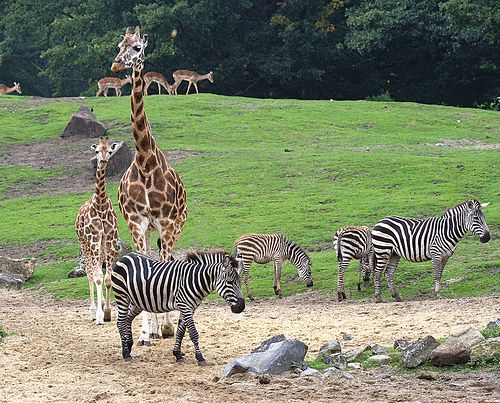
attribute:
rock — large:
[61, 104, 112, 141]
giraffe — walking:
[42, 21, 238, 361]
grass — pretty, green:
[188, 108, 423, 206]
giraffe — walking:
[71, 115, 124, 308]